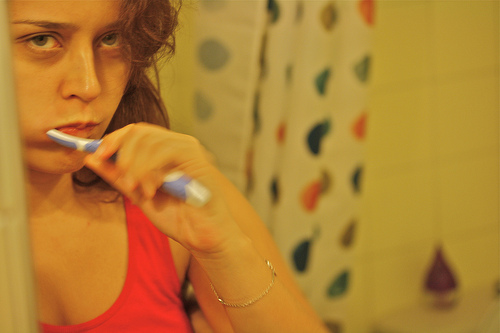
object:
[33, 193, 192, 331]
shirt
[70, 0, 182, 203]
hair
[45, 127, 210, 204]
toothbrush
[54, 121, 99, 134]
lip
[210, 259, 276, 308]
bracelet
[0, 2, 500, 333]
mirror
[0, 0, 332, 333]
woman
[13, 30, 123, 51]
eyes